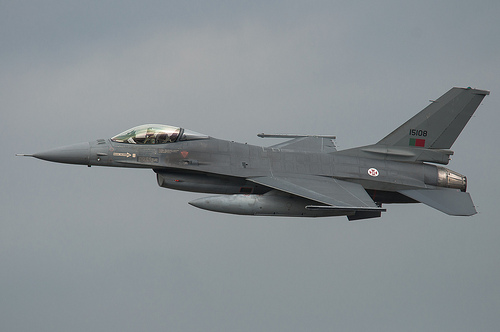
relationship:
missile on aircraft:
[189, 182, 364, 242] [19, 82, 489, 222]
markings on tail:
[408, 128, 427, 146] [373, 87, 486, 147]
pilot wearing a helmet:
[142, 125, 156, 145] [144, 125, 155, 134]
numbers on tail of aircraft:
[389, 130, 463, 170] [78, 80, 478, 227]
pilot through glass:
[142, 125, 156, 145] [108, 117, 211, 146]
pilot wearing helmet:
[142, 125, 156, 144] [147, 125, 154, 133]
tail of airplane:
[374, 75, 490, 162] [18, 72, 495, 257]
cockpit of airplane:
[119, 128, 194, 149] [13, 77, 484, 246]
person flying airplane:
[141, 127, 161, 149] [14, 80, 489, 226]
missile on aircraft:
[188, 182, 364, 218] [19, 82, 489, 241]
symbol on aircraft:
[366, 165, 380, 180] [14, 85, 490, 222]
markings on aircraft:
[408, 128, 428, 147] [14, 85, 490, 222]